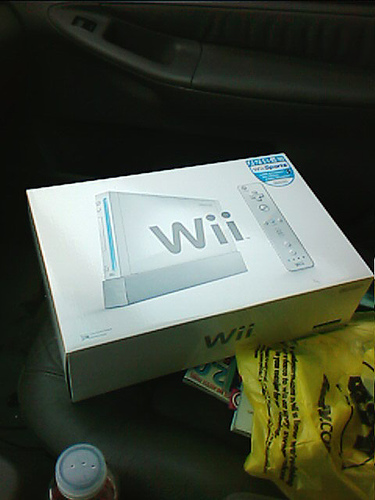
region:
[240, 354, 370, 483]
the bag is yellow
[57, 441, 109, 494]
the cap is plastic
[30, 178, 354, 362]
box is for a Wii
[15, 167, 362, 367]
the box is white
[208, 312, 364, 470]
a bag in a car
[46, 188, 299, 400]
a wii box in car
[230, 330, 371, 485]
a yellow plastic bag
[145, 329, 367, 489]
books on car seat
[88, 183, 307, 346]
a white wii box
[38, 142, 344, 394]
this is a wii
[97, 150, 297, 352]
this is a nintendo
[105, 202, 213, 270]
the wii is white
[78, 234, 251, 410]
the box is white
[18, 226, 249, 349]
the box is cardboard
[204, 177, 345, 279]
this is a wii remote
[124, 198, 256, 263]
the writing is gray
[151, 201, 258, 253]
the text is gray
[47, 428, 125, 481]
this is a bottle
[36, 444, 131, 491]
the bottle is plastic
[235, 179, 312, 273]
depiction of remote on box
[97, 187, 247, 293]
depiction of console on box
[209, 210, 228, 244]
letter i on box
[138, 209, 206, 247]
letter w on box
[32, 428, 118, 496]
bottle of drink below box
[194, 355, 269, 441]
stack of magazines beneath box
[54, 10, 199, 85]
door handle above box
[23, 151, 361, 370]
box resting on car seat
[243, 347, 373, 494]
yellow bag right of box